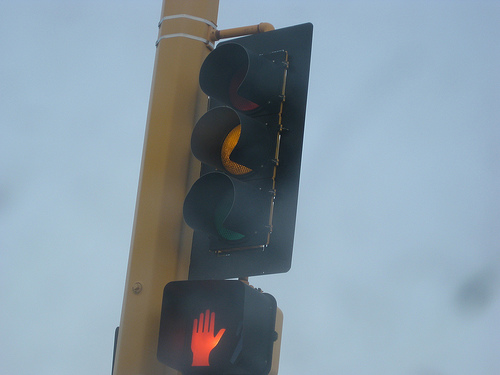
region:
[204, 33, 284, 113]
red light on traffic signal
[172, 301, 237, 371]
red do not walk signal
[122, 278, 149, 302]
small bolt on side of traffic light pole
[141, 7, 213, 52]
silver metal bracket on traffic light pole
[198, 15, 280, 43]
beige pole connecting to traffic signal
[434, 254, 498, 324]
small black cloud in sky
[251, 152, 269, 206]
small bolts on black traffic light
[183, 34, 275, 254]
black light guards on traffic signal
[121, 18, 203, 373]
large beige traffic signal pole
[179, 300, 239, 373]
orange hand sign on street post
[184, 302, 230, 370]
hand is lit up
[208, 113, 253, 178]
yellow light on street light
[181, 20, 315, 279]
street light is black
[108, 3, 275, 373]
street pole is yellow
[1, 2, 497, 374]
the sky is clear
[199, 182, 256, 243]
green light below yellow light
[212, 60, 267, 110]
red light above yellow light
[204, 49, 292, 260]
metal part around lights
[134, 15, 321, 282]
a traffic light on a yellow pole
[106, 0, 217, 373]
the pole if yellow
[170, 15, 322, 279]
traffic light is color black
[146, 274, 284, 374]
small peatonal traffic light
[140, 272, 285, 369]
traffic light is color black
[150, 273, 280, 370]
an orange hand on traffic light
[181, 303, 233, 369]
the orange hand is open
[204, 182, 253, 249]
green light of traffic light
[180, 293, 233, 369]
red signal light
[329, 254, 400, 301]
white clouds in blue sky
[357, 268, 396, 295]
white clouds in blue sky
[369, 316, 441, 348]
white clouds in blue sky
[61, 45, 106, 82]
white clouds in blue sky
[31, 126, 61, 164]
white clouds in blue sky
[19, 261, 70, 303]
white clouds in blue sky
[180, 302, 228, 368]
a hand that is put up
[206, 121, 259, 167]
a yellow sign to slow down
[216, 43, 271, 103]
a red light to stop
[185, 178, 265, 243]
a green sign to go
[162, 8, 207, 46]
two white straps on the pole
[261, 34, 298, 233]
a black frame around the lights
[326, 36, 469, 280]
there is a lot of fog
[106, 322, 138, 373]
there is a sign on the side of the pole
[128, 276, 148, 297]
one single bolt on the pole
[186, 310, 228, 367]
a hand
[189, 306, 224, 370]
a red hand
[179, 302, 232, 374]
a traffic signal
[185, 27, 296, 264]
a traffic signal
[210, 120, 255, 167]
a yellow light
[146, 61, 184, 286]
a yellow pole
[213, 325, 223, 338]
orange finger on hand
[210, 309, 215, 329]
orange finger on hand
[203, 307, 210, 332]
orange finger on hand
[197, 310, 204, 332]
orange finger on hand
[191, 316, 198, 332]
orange finger on hand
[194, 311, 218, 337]
orange fingers on hand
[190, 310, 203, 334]
orange fingers on hand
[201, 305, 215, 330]
orange fingers on hand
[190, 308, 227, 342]
orange fingers on hand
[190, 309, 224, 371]
orange colored stop hand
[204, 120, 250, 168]
yellow light on traffic signal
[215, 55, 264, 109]
red light on traffic signal